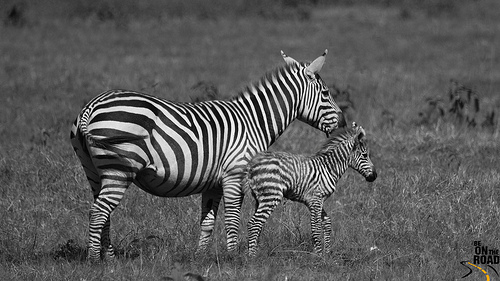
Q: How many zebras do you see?
A: 2.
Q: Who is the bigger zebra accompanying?
A: The baby zebra.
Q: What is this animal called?
A: Zebra.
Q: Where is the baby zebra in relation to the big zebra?
A: In front.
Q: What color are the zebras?
A: Black and white.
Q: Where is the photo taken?
A: At a safari.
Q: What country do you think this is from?
A: Africa.